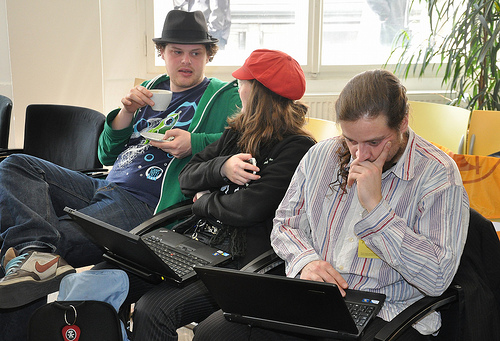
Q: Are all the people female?
A: No, they are both male and female.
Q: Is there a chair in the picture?
A: Yes, there is a chair.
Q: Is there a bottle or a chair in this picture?
A: Yes, there is a chair.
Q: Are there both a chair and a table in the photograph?
A: No, there is a chair but no tables.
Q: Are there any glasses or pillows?
A: No, there are no glasses or pillows.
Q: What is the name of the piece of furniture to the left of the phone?
A: The piece of furniture is a chair.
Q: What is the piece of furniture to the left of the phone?
A: The piece of furniture is a chair.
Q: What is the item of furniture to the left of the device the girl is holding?
A: The piece of furniture is a chair.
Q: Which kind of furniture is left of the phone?
A: The piece of furniture is a chair.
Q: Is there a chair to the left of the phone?
A: Yes, there is a chair to the left of the phone.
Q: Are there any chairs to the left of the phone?
A: Yes, there is a chair to the left of the phone.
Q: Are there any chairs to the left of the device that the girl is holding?
A: Yes, there is a chair to the left of the phone.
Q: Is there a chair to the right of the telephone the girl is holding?
A: No, the chair is to the left of the phone.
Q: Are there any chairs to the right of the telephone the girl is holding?
A: No, the chair is to the left of the phone.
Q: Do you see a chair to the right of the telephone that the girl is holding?
A: No, the chair is to the left of the phone.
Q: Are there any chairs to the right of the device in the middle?
A: No, the chair is to the left of the phone.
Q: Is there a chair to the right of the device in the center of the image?
A: No, the chair is to the left of the phone.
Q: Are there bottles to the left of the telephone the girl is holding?
A: No, there is a chair to the left of the telephone.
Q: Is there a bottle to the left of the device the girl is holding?
A: No, there is a chair to the left of the telephone.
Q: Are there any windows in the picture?
A: Yes, there is a window.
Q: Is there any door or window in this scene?
A: Yes, there is a window.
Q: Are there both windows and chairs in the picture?
A: Yes, there are both a window and a chair.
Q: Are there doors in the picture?
A: No, there are no doors.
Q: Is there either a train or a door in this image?
A: No, there are no doors or trains.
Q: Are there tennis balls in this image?
A: No, there are no tennis balls.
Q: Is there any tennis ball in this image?
A: No, there are no tennis balls.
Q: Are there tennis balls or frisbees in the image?
A: No, there are no tennis balls or frisbees.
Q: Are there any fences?
A: No, there are no fences.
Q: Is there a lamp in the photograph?
A: No, there are no lamps.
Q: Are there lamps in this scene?
A: No, there are no lamps.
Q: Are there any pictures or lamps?
A: No, there are no lamps or pictures.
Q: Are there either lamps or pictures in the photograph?
A: No, there are no lamps or pictures.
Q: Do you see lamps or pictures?
A: No, there are no lamps or pictures.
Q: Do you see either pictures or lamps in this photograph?
A: No, there are no lamps or pictures.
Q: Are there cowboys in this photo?
A: No, there are no cowboys.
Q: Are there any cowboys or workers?
A: No, there are no cowboys or workers.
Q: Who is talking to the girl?
A: The guy is talking to the girl.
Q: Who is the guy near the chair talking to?
A: The guy is talking to a girl.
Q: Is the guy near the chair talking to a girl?
A: Yes, the guy is talking to a girl.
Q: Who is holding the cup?
A: The guy is holding the cup.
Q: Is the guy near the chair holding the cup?
A: Yes, the guy is holding the cup.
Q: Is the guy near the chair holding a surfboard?
A: No, the guy is holding the cup.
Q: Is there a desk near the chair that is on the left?
A: No, there is a guy near the chair.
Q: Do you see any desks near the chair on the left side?
A: No, there is a guy near the chair.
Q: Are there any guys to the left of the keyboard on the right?
A: Yes, there is a guy to the left of the keyboard.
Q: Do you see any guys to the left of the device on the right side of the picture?
A: Yes, there is a guy to the left of the keyboard.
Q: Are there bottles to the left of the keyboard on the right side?
A: No, there is a guy to the left of the keyboard.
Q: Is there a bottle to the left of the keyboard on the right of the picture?
A: No, there is a guy to the left of the keyboard.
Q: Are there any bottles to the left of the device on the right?
A: No, there is a guy to the left of the keyboard.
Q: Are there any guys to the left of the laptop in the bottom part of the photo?
A: Yes, there is a guy to the left of the laptop.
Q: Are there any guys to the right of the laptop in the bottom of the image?
A: No, the guy is to the left of the laptop computer.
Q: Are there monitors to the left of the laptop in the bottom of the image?
A: No, there is a guy to the left of the laptop.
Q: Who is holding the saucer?
A: The guy is holding the saucer.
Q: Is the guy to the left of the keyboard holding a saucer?
A: Yes, the guy is holding a saucer.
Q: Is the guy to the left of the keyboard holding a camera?
A: No, the guy is holding a saucer.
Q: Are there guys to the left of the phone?
A: Yes, there is a guy to the left of the phone.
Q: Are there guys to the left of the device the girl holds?
A: Yes, there is a guy to the left of the phone.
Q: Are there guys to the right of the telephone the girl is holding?
A: No, the guy is to the left of the phone.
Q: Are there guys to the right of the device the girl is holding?
A: No, the guy is to the left of the phone.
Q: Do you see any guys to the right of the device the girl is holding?
A: No, the guy is to the left of the phone.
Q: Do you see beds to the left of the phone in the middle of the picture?
A: No, there is a guy to the left of the phone.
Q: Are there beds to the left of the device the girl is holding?
A: No, there is a guy to the left of the phone.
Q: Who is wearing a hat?
A: The guy is wearing a hat.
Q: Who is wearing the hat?
A: The guy is wearing a hat.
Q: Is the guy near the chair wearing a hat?
A: Yes, the guy is wearing a hat.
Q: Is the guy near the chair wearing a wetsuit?
A: No, the guy is wearing a hat.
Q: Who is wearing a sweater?
A: The guy is wearing a sweater.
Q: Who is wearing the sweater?
A: The guy is wearing a sweater.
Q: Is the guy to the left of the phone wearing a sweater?
A: Yes, the guy is wearing a sweater.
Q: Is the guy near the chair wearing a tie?
A: No, the guy is wearing a sweater.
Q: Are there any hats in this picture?
A: Yes, there is a hat.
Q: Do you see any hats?
A: Yes, there is a hat.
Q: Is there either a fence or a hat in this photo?
A: Yes, there is a hat.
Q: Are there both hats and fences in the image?
A: No, there is a hat but no fences.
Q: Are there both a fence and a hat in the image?
A: No, there is a hat but no fences.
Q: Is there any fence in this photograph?
A: No, there are no fences.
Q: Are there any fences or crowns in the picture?
A: No, there are no fences or crowns.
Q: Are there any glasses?
A: No, there are no glasses.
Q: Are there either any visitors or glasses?
A: No, there are no glasses or visitors.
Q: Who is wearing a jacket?
A: The girl is wearing a jacket.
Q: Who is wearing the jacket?
A: The girl is wearing a jacket.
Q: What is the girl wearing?
A: The girl is wearing a jacket.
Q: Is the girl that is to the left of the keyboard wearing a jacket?
A: Yes, the girl is wearing a jacket.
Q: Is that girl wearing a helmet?
A: No, the girl is wearing a jacket.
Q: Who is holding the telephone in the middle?
A: The girl is holding the phone.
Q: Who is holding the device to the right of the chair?
A: The girl is holding the phone.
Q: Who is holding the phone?
A: The girl is holding the phone.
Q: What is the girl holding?
A: The girl is holding the telephone.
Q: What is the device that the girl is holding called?
A: The device is a phone.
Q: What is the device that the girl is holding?
A: The device is a phone.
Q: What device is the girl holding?
A: The girl is holding the phone.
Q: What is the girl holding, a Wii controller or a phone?
A: The girl is holding a phone.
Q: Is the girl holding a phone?
A: Yes, the girl is holding a phone.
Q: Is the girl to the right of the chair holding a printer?
A: No, the girl is holding a phone.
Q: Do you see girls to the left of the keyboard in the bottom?
A: Yes, there is a girl to the left of the keyboard.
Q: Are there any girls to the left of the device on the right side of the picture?
A: Yes, there is a girl to the left of the keyboard.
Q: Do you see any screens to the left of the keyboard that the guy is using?
A: No, there is a girl to the left of the keyboard.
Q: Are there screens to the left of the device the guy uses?
A: No, there is a girl to the left of the keyboard.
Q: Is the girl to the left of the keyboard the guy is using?
A: Yes, the girl is to the left of the keyboard.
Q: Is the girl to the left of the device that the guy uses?
A: Yes, the girl is to the left of the keyboard.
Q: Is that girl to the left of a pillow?
A: No, the girl is to the left of the keyboard.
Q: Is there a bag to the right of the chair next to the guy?
A: No, there is a girl to the right of the chair.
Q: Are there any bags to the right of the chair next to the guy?
A: No, there is a girl to the right of the chair.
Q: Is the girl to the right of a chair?
A: Yes, the girl is to the right of a chair.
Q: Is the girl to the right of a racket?
A: No, the girl is to the right of a chair.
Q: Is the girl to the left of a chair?
A: No, the girl is to the right of a chair.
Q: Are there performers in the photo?
A: No, there are no performers.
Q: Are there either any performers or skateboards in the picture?
A: No, there are no performers or skateboards.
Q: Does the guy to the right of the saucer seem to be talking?
A: Yes, the guy is talking.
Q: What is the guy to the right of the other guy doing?
A: The guy is talking.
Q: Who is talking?
A: The guy is talking.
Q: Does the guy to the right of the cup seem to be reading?
A: No, the guy is talking.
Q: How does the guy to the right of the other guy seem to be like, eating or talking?
A: The guy is talking.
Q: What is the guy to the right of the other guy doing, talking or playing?
A: The guy is talking.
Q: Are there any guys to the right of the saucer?
A: Yes, there is a guy to the right of the saucer.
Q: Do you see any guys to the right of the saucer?
A: Yes, there is a guy to the right of the saucer.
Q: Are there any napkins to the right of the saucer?
A: No, there is a guy to the right of the saucer.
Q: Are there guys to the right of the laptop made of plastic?
A: Yes, there is a guy to the right of the laptop.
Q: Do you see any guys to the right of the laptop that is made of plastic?
A: Yes, there is a guy to the right of the laptop.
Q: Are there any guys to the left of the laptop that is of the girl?
A: No, the guy is to the right of the laptop.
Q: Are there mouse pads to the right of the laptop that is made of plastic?
A: No, there is a guy to the right of the laptop computer.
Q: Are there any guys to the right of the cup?
A: Yes, there is a guy to the right of the cup.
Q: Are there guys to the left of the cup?
A: No, the guy is to the right of the cup.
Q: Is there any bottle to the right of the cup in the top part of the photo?
A: No, there is a guy to the right of the cup.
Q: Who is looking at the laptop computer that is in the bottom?
A: The guy is looking at the laptop computer.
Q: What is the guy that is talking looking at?
A: The guy is looking at the laptop.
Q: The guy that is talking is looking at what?
A: The guy is looking at the laptop.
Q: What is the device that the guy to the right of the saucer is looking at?
A: The device is a laptop.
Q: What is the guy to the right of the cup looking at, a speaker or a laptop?
A: The guy is looking at a laptop.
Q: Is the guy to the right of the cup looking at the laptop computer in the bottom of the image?
A: Yes, the guy is looking at the laptop computer.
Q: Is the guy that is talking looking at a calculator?
A: No, the guy is looking at the laptop computer.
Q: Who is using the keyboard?
A: The guy is using the keyboard.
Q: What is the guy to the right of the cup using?
A: The guy is using a keyboard.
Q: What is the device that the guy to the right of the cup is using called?
A: The device is a keyboard.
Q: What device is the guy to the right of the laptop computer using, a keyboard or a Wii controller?
A: The guy is using a keyboard.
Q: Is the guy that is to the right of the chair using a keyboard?
A: Yes, the guy is using a keyboard.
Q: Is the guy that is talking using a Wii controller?
A: No, the guy is using a keyboard.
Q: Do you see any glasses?
A: No, there are no glasses.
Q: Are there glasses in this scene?
A: No, there are no glasses.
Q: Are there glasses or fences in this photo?
A: No, there are no glasses or fences.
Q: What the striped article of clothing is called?
A: The clothing item is a shirt.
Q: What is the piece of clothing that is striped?
A: The clothing item is a shirt.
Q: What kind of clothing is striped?
A: The clothing is a shirt.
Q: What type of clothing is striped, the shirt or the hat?
A: The shirt is striped.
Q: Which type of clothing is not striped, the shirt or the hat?
A: The hat is not striped.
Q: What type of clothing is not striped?
A: The clothing is a hat.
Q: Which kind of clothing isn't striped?
A: The clothing is a hat.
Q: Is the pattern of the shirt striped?
A: Yes, the shirt is striped.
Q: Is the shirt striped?
A: Yes, the shirt is striped.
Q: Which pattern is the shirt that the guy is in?
A: The shirt is striped.